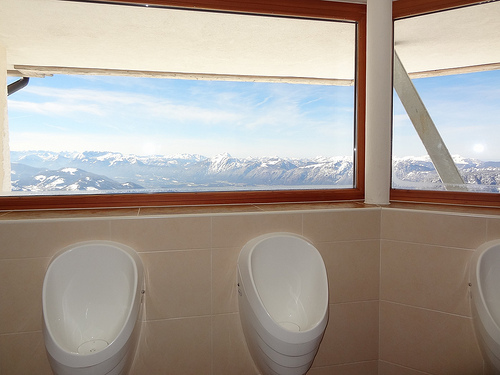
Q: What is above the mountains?
A: White clouds in the blue sky.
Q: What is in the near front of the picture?
A: White urinals.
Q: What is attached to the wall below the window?
A: White urinal.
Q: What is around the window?
A: A brown wooden frame.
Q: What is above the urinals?
A: A glass window.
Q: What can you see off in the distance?
A: A large mountain range.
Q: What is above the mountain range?
A: A blue and white sky.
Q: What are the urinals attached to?
A: A tan tile wall.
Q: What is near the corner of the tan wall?
A: A white urinal.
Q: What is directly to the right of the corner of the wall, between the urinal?
A: A tan brick in the wall.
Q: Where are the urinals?
A: Under the window.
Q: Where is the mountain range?
A: In the distance.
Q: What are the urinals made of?
A: Ceramic.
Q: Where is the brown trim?
A: Around the window.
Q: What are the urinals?
A: White.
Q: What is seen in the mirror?
A: The reflection.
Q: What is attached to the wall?
A: The urinals.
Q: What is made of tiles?
A: The wall.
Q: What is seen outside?
A: The mountains.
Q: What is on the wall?
A: The white urinal.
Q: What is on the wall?
A: Beige tile.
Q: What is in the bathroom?
A: The window.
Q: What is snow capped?
A: Mountains.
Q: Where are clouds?
A: In the sky.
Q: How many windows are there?
A: Two.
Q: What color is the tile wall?
A: Tan.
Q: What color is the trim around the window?
A: Brown.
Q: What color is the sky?
A: Blue and white.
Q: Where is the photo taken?
A: In a bathroom.